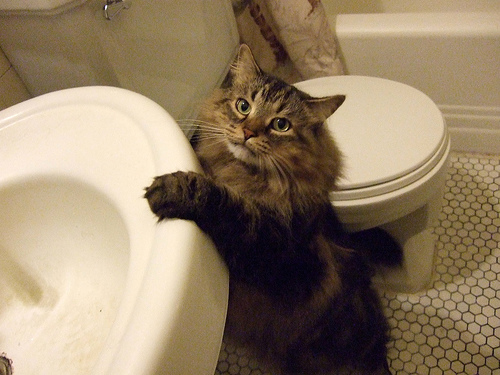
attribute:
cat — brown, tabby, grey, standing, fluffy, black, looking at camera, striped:
[145, 43, 391, 374]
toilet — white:
[1, 0, 450, 294]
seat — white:
[287, 75, 450, 203]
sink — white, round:
[1, 85, 230, 375]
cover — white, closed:
[288, 76, 444, 191]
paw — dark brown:
[148, 170, 274, 284]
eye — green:
[236, 97, 251, 117]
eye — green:
[270, 117, 293, 132]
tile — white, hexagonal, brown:
[215, 151, 500, 375]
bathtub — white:
[328, 0, 499, 155]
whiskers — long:
[182, 117, 300, 195]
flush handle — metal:
[103, 0, 133, 21]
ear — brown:
[233, 44, 264, 89]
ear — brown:
[306, 94, 347, 126]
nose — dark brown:
[241, 125, 258, 140]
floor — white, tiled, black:
[216, 125, 500, 374]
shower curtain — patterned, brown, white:
[233, 0, 349, 85]